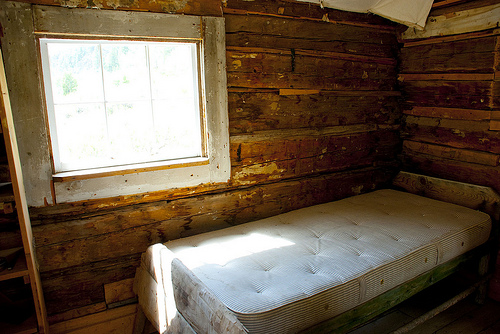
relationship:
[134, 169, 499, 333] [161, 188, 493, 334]
bed has a mattress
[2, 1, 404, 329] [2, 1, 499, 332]
wall in a cabin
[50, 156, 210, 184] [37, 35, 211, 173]
sill below window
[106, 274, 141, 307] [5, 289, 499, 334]
board on floor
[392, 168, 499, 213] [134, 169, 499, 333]
headboard attached to bed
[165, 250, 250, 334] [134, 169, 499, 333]
footboard connected to bed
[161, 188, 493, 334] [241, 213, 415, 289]
mattress has buttons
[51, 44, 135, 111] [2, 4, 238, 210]
tree through window